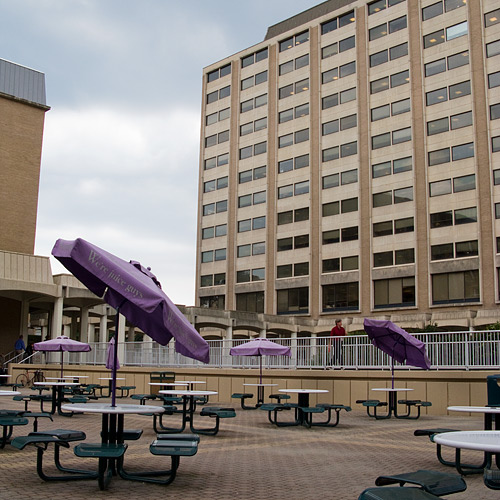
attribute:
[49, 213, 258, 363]
umbrella — purple, over, tilted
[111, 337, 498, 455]
patio — brick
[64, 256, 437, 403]
umbrellas — purple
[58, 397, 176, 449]
table — outdoor, dining, white, green, round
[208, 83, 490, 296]
building — large, tan, highrise, here, tall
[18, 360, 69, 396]
bike — here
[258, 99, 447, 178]
windows — small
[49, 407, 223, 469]
seats — attached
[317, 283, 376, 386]
man — walking, wearing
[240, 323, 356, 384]
fencing — white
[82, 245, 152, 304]
writing — white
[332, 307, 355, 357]
shirt — red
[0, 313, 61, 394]
person — climbing, wearing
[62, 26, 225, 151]
cloud — puffy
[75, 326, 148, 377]
umbrella — closed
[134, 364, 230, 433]
can — brown, garbage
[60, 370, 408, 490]
tables — picnic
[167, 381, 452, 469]
seating — outdoor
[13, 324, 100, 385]
man — walking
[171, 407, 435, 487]
layout — brick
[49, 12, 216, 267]
sky — here, blue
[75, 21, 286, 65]
clouds — here